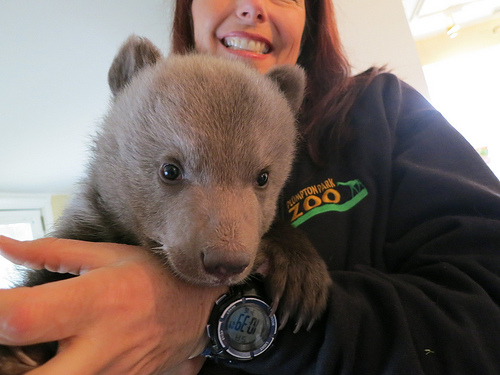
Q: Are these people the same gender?
A: Yes, all the people are female.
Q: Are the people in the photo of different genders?
A: No, all the people are female.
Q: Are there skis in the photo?
A: No, there are no skis.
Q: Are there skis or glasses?
A: No, there are no skis or glasses.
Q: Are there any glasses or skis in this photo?
A: No, there are no skis or glasses.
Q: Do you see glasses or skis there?
A: No, there are no skis or glasses.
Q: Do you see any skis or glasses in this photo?
A: No, there are no skis or glasses.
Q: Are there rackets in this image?
A: No, there are no rackets.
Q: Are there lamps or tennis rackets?
A: No, there are no tennis rackets or lamps.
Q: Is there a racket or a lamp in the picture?
A: No, there are no rackets or lamps.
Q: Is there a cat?
A: No, there are no cats.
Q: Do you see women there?
A: Yes, there is a woman.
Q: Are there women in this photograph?
A: Yes, there is a woman.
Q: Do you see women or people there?
A: Yes, there is a woman.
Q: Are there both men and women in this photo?
A: No, there is a woman but no men.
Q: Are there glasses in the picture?
A: No, there are no glasses.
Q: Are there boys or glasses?
A: No, there are no glasses or boys.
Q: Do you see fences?
A: No, there are no fences.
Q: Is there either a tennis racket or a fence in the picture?
A: No, there are no fences or rackets.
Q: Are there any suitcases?
A: No, there are no suitcases.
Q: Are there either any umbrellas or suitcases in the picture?
A: No, there are no suitcases or umbrellas.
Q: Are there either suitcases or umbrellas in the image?
A: No, there are no suitcases or umbrellas.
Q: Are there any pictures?
A: No, there are no pictures.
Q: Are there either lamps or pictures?
A: No, there are no pictures or lamps.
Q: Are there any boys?
A: No, there are no boys.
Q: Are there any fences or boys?
A: No, there are no boys or fences.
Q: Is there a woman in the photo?
A: Yes, there is a woman.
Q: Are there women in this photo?
A: Yes, there is a woman.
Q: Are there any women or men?
A: Yes, there is a woman.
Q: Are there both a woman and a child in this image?
A: No, there is a woman but no children.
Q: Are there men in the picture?
A: No, there are no men.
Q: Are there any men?
A: No, there are no men.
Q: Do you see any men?
A: No, there are no men.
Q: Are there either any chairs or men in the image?
A: No, there are no men or chairs.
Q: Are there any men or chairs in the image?
A: No, there are no men or chairs.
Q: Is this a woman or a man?
A: This is a woman.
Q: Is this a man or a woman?
A: This is a woman.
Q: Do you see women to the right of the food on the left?
A: Yes, there is a woman to the right of the food.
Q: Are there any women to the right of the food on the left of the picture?
A: Yes, there is a woman to the right of the food.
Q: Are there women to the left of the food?
A: No, the woman is to the right of the food.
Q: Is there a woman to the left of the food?
A: No, the woman is to the right of the food.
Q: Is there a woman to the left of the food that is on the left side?
A: No, the woman is to the right of the food.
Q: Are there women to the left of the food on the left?
A: No, the woman is to the right of the food.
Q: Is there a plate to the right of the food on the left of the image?
A: No, there is a woman to the right of the food.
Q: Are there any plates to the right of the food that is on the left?
A: No, there is a woman to the right of the food.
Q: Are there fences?
A: No, there are no fences.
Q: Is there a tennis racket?
A: No, there are no rackets.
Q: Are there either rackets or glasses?
A: No, there are no rackets or glasses.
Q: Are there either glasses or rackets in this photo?
A: No, there are no rackets or glasses.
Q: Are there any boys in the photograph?
A: No, there are no boys.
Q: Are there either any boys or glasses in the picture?
A: No, there are no boys or glasses.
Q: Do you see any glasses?
A: No, there are no glasses.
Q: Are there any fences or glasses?
A: No, there are no glasses or fences.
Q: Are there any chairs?
A: No, there are no chairs.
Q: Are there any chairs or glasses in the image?
A: No, there are no chairs or glasses.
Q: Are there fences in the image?
A: No, there are no fences.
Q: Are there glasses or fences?
A: No, there are no fences or glasses.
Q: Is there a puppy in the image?
A: Yes, there is a puppy.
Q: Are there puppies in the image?
A: Yes, there is a puppy.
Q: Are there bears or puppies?
A: Yes, there is a puppy.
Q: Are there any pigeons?
A: No, there are no pigeons.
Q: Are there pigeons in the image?
A: No, there are no pigeons.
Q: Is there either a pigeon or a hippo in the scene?
A: No, there are no pigeons or hippos.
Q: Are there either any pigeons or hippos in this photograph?
A: No, there are no pigeons or hippos.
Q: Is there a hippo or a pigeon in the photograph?
A: No, there are no pigeons or hippos.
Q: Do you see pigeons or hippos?
A: No, there are no pigeons or hippos.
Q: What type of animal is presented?
A: The animal is a puppy.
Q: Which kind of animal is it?
A: The animal is a puppy.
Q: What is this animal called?
A: This is a puppy.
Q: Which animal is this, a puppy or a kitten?
A: This is a puppy.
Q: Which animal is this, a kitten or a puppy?
A: This is a puppy.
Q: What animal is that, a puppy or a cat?
A: That is a puppy.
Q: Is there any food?
A: Yes, there is food.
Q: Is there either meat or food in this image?
A: Yes, there is food.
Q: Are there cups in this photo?
A: No, there are no cups.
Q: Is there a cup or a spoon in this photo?
A: No, there are no cups or spoons.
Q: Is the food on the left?
A: Yes, the food is on the left of the image.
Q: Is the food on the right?
A: No, the food is on the left of the image.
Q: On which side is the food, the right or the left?
A: The food is on the left of the image.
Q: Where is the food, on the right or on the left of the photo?
A: The food is on the left of the image.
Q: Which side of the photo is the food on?
A: The food is on the left of the image.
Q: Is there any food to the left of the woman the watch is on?
A: Yes, there is food to the left of the woman.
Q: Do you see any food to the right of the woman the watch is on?
A: No, the food is to the left of the woman.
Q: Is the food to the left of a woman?
A: Yes, the food is to the left of a woman.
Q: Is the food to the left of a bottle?
A: No, the food is to the left of a woman.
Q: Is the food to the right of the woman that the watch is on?
A: No, the food is to the left of the woman.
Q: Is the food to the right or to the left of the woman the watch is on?
A: The food is to the left of the woman.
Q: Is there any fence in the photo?
A: No, there are no fences.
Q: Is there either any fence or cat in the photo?
A: No, there are no fences or cats.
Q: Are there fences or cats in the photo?
A: No, there are no fences or cats.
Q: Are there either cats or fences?
A: No, there are no fences or cats.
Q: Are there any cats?
A: No, there are no cats.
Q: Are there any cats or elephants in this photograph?
A: No, there are no cats or elephants.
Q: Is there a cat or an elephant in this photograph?
A: No, there are no cats or elephants.